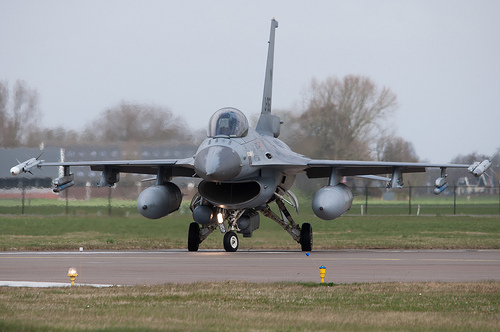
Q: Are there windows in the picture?
A: Yes, there is a window.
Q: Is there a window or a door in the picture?
A: Yes, there is a window.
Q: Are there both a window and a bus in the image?
A: No, there is a window but no buses.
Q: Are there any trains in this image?
A: No, there are no trains.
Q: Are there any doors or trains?
A: No, there are no trains or doors.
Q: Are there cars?
A: No, there are no cars.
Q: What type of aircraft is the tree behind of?
A: The tree is behind the airplane.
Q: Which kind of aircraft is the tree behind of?
A: The tree is behind the airplane.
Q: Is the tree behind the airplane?
A: Yes, the tree is behind the airplane.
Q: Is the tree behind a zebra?
A: No, the tree is behind the airplane.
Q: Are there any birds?
A: No, there are no birds.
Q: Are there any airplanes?
A: Yes, there is an airplane.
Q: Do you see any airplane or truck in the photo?
A: Yes, there is an airplane.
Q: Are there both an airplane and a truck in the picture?
A: No, there is an airplane but no trucks.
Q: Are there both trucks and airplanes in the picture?
A: No, there is an airplane but no trucks.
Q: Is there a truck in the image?
A: No, there are no trucks.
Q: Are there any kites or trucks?
A: No, there are no trucks or kites.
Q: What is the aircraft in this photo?
A: The aircraft is an airplane.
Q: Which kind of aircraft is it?
A: The aircraft is an airplane.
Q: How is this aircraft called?
A: This is an airplane.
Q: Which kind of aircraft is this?
A: This is an airplane.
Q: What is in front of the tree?
A: The plane is in front of the tree.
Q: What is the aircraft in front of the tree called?
A: The aircraft is an airplane.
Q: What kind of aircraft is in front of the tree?
A: The aircraft is an airplane.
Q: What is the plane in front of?
A: The plane is in front of the tree.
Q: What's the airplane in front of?
A: The plane is in front of the tree.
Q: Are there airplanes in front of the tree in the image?
A: Yes, there is an airplane in front of the tree.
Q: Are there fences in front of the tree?
A: No, there is an airplane in front of the tree.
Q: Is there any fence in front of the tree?
A: No, there is an airplane in front of the tree.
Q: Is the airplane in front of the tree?
A: Yes, the airplane is in front of the tree.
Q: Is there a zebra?
A: No, there are no zebras.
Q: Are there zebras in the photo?
A: No, there are no zebras.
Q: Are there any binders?
A: No, there are no binders.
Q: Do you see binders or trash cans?
A: No, there are no binders or trash cans.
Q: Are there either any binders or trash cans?
A: No, there are no binders or trash cans.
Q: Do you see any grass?
A: Yes, there is grass.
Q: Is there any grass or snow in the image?
A: Yes, there is grass.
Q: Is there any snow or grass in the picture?
A: Yes, there is grass.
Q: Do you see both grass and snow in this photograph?
A: No, there is grass but no snow.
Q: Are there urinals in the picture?
A: No, there are no urinals.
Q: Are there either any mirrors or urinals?
A: No, there are no urinals or mirrors.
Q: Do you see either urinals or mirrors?
A: No, there are no urinals or mirrors.